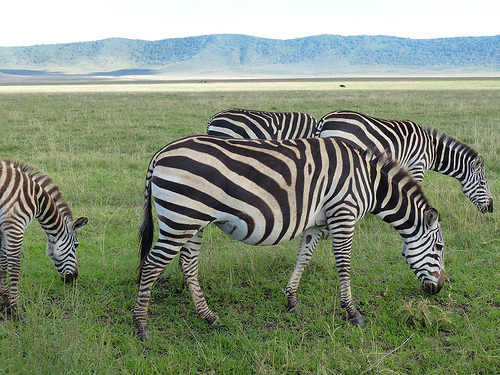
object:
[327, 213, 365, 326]
leg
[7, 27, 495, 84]
trees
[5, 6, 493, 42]
sky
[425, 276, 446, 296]
mouth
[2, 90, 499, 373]
grass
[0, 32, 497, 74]
hills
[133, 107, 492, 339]
they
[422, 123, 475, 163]
mane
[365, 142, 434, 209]
mane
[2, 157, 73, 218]
mane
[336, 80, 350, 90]
animal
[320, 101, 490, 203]
zebra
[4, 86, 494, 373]
field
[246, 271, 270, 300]
part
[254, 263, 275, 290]
part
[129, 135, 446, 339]
zebra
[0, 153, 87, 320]
zebra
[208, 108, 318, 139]
zebra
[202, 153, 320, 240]
stripes